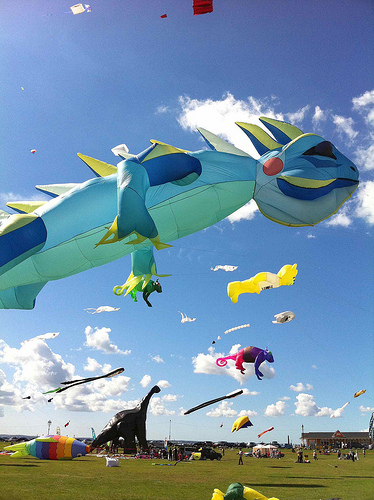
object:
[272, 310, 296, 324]
kite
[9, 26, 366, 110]
sky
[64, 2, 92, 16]
kite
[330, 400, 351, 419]
kite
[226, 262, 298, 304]
kite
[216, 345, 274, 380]
kite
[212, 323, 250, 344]
kite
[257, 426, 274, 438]
kite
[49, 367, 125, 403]
kite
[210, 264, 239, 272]
kite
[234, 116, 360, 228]
dragon-head balloon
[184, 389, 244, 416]
kite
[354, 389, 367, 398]
kite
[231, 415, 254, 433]
kite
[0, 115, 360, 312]
dinosaur